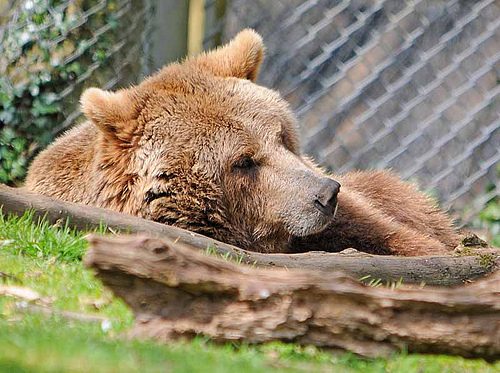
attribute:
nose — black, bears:
[312, 175, 344, 215]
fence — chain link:
[270, 0, 497, 186]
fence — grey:
[259, 33, 487, 200]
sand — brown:
[3, 281, 115, 337]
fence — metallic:
[351, 17, 469, 99]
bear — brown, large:
[24, 25, 455, 254]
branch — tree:
[5, 183, 499, 284]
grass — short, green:
[0, 204, 499, 371]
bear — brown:
[21, 23, 477, 264]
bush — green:
[3, 0, 150, 190]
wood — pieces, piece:
[83, 234, 498, 359]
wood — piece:
[1, 182, 499, 286]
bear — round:
[75, 60, 459, 269]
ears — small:
[71, 20, 264, 129]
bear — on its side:
[29, 17, 498, 304]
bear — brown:
[46, 64, 385, 274]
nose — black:
[305, 172, 382, 270]